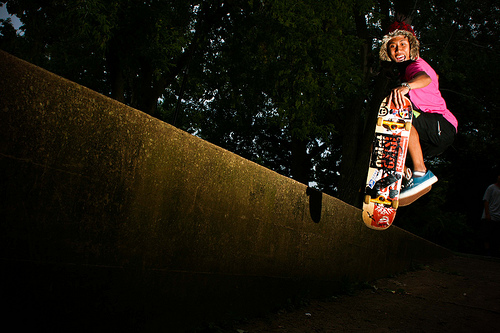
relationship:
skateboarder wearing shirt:
[377, 22, 459, 208] [404, 57, 458, 134]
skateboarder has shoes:
[377, 22, 459, 208] [397, 169, 438, 208]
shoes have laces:
[397, 169, 438, 208] [403, 167, 413, 181]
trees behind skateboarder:
[0, 1, 497, 241] [377, 22, 459, 208]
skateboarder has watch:
[377, 22, 459, 208] [400, 81, 411, 92]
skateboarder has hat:
[377, 22, 459, 208] [380, 21, 420, 63]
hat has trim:
[380, 21, 420, 63] [380, 30, 420, 63]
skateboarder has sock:
[377, 22, 459, 208] [413, 170, 427, 178]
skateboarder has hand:
[377, 22, 459, 208] [386, 86, 412, 110]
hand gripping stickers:
[386, 86, 412, 110] [361, 95, 415, 231]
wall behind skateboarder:
[0, 48, 453, 333] [377, 22, 459, 208]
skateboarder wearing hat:
[377, 22, 459, 208] [380, 21, 420, 63]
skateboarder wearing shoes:
[377, 22, 459, 208] [397, 169, 438, 208]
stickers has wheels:
[361, 95, 415, 231] [364, 117, 412, 210]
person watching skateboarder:
[480, 176, 499, 257] [377, 22, 459, 208]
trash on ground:
[304, 311, 312, 317] [213, 252, 499, 333]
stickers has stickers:
[361, 95, 415, 231] [361, 91, 415, 230]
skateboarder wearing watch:
[377, 22, 459, 208] [400, 81, 411, 92]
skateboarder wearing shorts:
[377, 22, 459, 208] [412, 113, 457, 159]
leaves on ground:
[235, 263, 472, 333] [213, 252, 499, 333]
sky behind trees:
[1, 0, 499, 208] [0, 1, 497, 241]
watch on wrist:
[400, 81, 411, 92] [402, 82, 413, 93]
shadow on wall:
[306, 184, 323, 225] [0, 48, 453, 333]